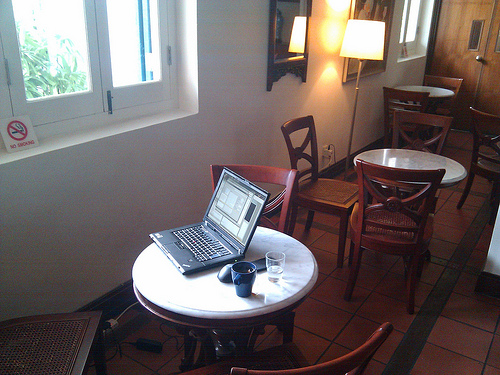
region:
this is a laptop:
[169, 193, 260, 270]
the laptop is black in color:
[176, 248, 195, 271]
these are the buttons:
[187, 230, 199, 253]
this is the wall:
[98, 145, 162, 188]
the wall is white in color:
[49, 189, 99, 238]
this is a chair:
[355, 178, 432, 269]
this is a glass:
[264, 254, 287, 276]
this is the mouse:
[216, 262, 231, 281]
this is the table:
[186, 289, 227, 307]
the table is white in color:
[165, 289, 200, 301]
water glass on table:
[252, 251, 280, 301]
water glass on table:
[261, 228, 309, 303]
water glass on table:
[267, 244, 299, 289]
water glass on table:
[258, 254, 298, 312]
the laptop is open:
[138, 140, 238, 296]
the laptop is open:
[145, 167, 281, 328]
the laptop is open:
[165, 215, 305, 370]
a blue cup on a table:
[224, 255, 259, 305]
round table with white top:
[121, 222, 320, 369]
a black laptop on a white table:
[142, 159, 274, 277]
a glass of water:
[258, 243, 292, 286]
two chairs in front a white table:
[279, 103, 474, 314]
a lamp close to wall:
[326, 6, 398, 160]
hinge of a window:
[91, 85, 123, 124]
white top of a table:
[346, 135, 473, 196]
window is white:
[0, 0, 212, 154]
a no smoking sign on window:
[3, 112, 46, 160]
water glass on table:
[265, 247, 282, 277]